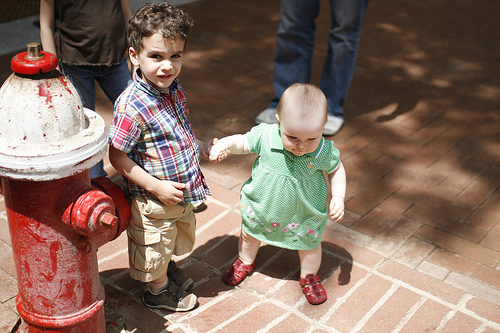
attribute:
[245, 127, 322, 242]
dress — green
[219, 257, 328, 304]
sandal's — red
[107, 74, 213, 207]
shirt — plaid, here, multicolored, striped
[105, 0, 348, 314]
two children — standing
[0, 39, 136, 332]
fire hydrant — white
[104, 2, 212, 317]
boy — little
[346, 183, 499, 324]
bricks — here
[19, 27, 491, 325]
ground — here, brown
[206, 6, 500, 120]
shade — here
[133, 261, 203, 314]
shoes — here, black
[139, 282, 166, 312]
ankle — here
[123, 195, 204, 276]
pants — brown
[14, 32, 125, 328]
water pump — old, red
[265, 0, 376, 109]
pants — blue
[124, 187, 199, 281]
shorts — brown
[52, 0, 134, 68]
shirt — brown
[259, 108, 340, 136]
shoes — white